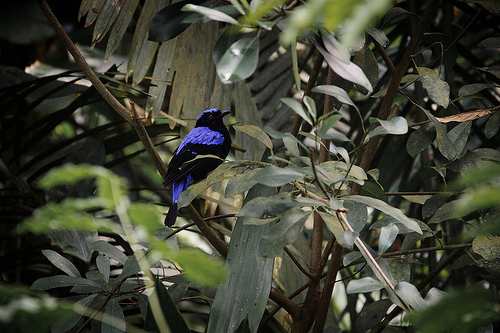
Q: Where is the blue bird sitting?
A: In a tree.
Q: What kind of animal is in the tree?
A: A bird.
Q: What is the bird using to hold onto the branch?
A: Feet.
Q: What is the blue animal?
A: A bird.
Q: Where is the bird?
A: In a tree.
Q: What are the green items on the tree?
A: Leaves.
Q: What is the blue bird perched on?
A: A branch.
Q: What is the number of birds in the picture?
A: One.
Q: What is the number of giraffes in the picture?
A: Zero.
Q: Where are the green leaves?
A: On the tree.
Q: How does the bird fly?
A: With it's wings.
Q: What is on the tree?
A: Green leaves.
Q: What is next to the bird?
A: Green leaves.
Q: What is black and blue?
A: A bird.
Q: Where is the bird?
A: On a thin brown branch.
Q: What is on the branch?
A: A bird.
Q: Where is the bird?
A: On the branch.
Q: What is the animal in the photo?
A: A bird.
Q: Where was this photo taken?
A: In the trees.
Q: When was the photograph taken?
A: During the daytime.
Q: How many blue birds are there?
A: One.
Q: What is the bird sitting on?
A: A tree.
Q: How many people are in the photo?
A: None.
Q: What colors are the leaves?
A: Green.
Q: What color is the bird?
A: Blue.